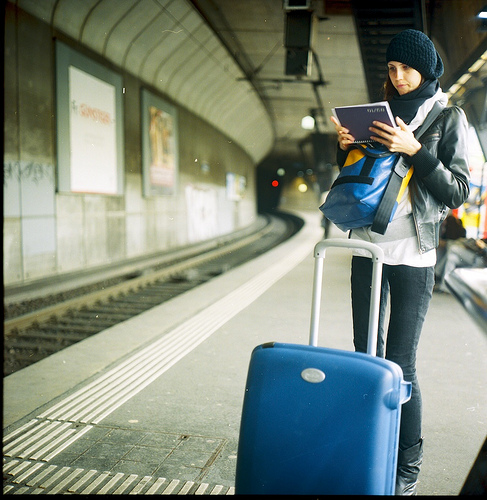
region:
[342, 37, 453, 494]
woman holding a notebook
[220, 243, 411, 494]
blue plastic travel case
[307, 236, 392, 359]
white handle of a travel case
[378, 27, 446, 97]
woman wearing a black hat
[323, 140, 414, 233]
blue and yellow bag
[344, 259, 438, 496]
skinny legs in dark pants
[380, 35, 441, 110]
woman with brown hair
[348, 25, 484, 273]
woman wearing a black jacket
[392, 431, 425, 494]
leathery black boot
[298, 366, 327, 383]
small silver label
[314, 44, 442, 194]
girl looking at a book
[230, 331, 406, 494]
blue hard shell suitcase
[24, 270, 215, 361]
train tracks by wall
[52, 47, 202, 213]
advertisements on the wall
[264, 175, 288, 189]
red light down the tunnel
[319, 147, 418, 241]
blue yellow and black bag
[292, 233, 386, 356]
pulling handle on suitcase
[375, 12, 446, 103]
girl wearing a knit hat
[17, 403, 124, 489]
bumps in the cement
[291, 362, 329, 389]
silver label on the suitcase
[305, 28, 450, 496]
A woman at a train station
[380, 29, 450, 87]
A woman wearing a hat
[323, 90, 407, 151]
A woman holding a book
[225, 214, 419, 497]
A blue suitcase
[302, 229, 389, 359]
A handle on a suitcase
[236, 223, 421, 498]
A blue suitcase with a white handle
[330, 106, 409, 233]
A blue bag in a woman's arms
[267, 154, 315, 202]
Lights in a train station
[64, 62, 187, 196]
Posters on the wall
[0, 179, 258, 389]
An empty train track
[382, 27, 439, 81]
a black knit cap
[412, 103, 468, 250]
a black leather jacket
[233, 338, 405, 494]
a blue hard shell suitcase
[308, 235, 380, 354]
grey color aluminum suitcase handle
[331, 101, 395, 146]
a black ring notebook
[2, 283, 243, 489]
white do not cross safety line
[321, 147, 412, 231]
a blue and yellow shoulder bag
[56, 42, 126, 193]
advertisement banner display on the wall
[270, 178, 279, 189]
the train signal light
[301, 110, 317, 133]
the train station ceiling light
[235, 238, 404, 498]
a blue hard suitcase with a white handle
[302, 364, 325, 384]
a silver logo on a blue suitcase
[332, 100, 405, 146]
a woman holding a purple notebook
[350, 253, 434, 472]
a woman wearing a pair of blue jeans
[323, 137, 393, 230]
woman holding a blue bag with yellow and black patterns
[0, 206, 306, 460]
a subway track in a subway station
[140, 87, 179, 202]
advertisement panel on the wall of a subway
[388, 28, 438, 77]
a woman wearing a black wool hat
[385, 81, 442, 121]
a woman wearing a black scarf around her neck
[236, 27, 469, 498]
a woman standing in a subway station with her suitcase